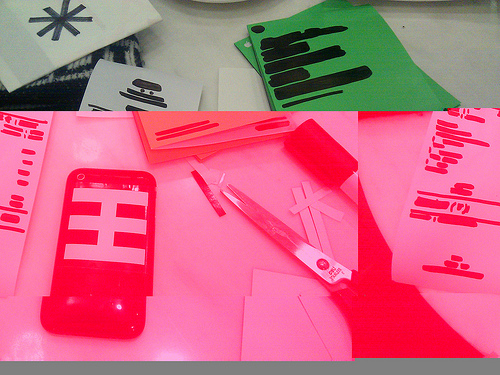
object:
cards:
[244, 4, 446, 111]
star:
[28, 0, 94, 42]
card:
[2, 1, 165, 92]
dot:
[251, 24, 266, 33]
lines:
[258, 24, 350, 52]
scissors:
[218, 183, 480, 358]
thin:
[190, 172, 226, 217]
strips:
[290, 186, 322, 252]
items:
[422, 166, 450, 176]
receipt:
[392, 108, 498, 291]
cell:
[48, 166, 157, 299]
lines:
[64, 188, 148, 205]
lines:
[154, 119, 212, 137]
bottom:
[132, 111, 297, 165]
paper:
[241, 267, 354, 360]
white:
[73, 187, 149, 207]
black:
[117, 204, 147, 221]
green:
[355, 26, 395, 62]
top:
[242, 2, 445, 110]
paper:
[289, 183, 332, 214]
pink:
[169, 223, 227, 328]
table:
[0, 110, 499, 374]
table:
[136, 0, 500, 113]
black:
[120, 77, 165, 109]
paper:
[78, 58, 206, 112]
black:
[268, 66, 312, 88]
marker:
[88, 77, 171, 112]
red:
[31, 226, 231, 336]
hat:
[0, 34, 146, 112]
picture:
[1, 110, 499, 357]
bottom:
[332, 269, 486, 357]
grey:
[123, 40, 136, 66]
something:
[282, 118, 360, 204]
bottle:
[281, 117, 361, 203]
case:
[38, 294, 147, 341]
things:
[309, 200, 345, 223]